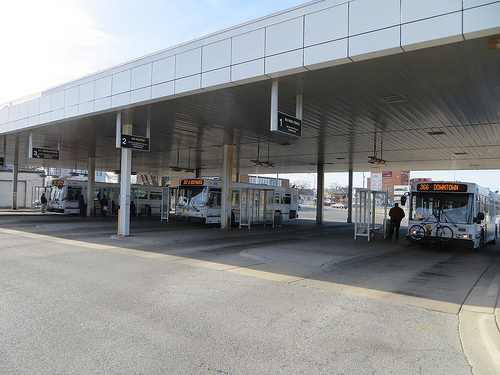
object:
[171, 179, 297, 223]
buses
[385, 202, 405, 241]
man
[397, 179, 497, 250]
bus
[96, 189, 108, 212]
people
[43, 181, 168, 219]
bus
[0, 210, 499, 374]
road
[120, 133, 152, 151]
signs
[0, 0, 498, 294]
terminal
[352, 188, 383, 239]
booth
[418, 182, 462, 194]
sign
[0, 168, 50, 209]
garage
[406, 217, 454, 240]
bike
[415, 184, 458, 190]
lettering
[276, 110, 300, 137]
sign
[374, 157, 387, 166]
lights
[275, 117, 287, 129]
number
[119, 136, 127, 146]
number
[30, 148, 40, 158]
number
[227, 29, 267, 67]
tiles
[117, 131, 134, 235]
pillar